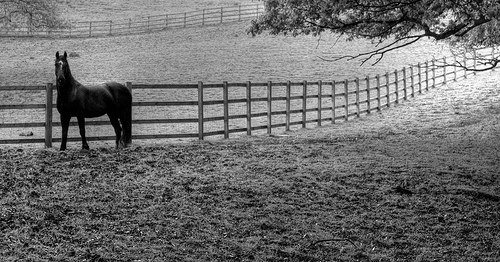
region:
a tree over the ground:
[242, 0, 499, 77]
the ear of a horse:
[61, 47, 68, 58]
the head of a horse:
[51, 49, 71, 89]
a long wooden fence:
[0, 42, 499, 148]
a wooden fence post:
[194, 77, 205, 141]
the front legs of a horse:
[55, 115, 90, 155]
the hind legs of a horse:
[104, 111, 135, 150]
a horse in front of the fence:
[51, 48, 133, 153]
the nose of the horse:
[56, 72, 68, 84]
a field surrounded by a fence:
[0, 0, 499, 152]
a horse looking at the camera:
[43, 33, 178, 173]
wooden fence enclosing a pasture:
[185, 69, 402, 129]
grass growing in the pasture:
[210, 195, 303, 238]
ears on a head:
[49, 43, 74, 60]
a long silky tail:
[124, 95, 138, 143]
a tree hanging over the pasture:
[256, 1, 490, 51]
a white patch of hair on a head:
[59, 58, 69, 65]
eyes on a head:
[48, 60, 74, 70]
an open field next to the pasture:
[134, 43, 249, 78]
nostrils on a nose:
[56, 74, 73, 80]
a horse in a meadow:
[47, 52, 142, 154]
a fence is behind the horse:
[0, 32, 497, 149]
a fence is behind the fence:
[1, 0, 279, 37]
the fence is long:
[0, 45, 497, 145]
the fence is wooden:
[2, 40, 497, 145]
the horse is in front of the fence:
[50, 51, 143, 161]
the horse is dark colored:
[47, 47, 137, 146]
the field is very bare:
[9, 67, 499, 260]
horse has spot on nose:
[53, 57, 73, 69]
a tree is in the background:
[2, 4, 84, 36]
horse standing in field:
[48, 42, 145, 144]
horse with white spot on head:
[25, 42, 142, 156]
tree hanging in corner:
[244, 0, 499, 112]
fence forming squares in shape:
[182, 72, 307, 152]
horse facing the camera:
[26, 43, 140, 172]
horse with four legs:
[11, 39, 169, 175]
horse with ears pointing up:
[41, 43, 168, 181]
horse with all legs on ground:
[31, 42, 151, 166]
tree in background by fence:
[19, 0, 94, 40]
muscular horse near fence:
[27, 41, 145, 160]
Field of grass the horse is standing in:
[10, 158, 488, 249]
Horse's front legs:
[58, 114, 90, 150]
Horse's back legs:
[108, 116, 133, 151]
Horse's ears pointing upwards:
[54, 49, 70, 58]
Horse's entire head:
[53, 50, 73, 87]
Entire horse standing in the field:
[53, 48, 136, 152]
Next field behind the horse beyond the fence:
[93, 42, 345, 74]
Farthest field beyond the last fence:
[65, 2, 172, 14]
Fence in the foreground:
[191, 73, 398, 134]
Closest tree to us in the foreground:
[242, 6, 494, 64]